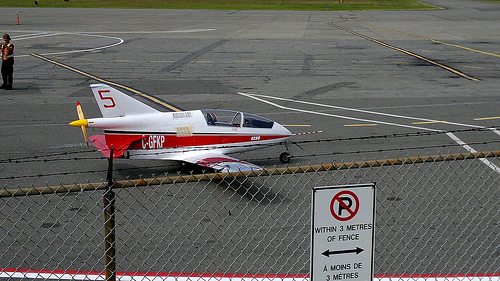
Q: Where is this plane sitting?
A: On an airport tarmac.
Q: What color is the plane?
A: Red and white.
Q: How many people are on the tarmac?
A: One.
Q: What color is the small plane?
A: Red white and yellow.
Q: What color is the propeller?
A: Yellow.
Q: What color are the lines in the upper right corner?
A: Yellow.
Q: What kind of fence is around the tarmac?
A: Chain link.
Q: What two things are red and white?
A: The plane and the sign.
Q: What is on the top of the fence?
A: Barbed wire.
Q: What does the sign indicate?
A: No parking.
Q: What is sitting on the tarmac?
A: The plane.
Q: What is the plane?
A: A small aircraft.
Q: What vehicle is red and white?
A: The plane.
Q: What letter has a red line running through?
A: P.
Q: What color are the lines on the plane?
A: Red.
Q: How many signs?
A: One.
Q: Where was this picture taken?
A: Airport.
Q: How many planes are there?
A: One plane.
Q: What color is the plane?
A: Red and white.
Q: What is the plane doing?
A: Parked.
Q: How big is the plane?
A: Very small.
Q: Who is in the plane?
A: It is empty.